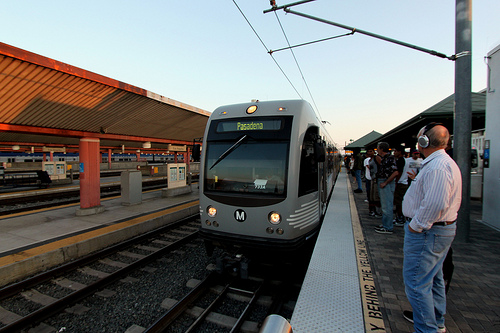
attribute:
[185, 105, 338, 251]
train — passenger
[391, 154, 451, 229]
shirt — white, stripped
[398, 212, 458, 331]
jeans — blue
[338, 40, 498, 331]
station — train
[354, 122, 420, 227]
people — large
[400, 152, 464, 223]
shirt — white, striped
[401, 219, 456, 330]
jeans — blue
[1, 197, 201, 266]
lines — yellow